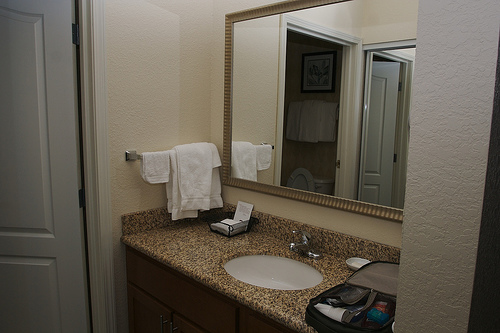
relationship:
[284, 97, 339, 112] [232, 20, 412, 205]
rack in mirror's reflection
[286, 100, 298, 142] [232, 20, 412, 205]
towels in mirror's reflection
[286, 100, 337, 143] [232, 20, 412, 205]
towels in mirror's reflection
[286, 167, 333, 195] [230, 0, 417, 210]
toilet reflected in mirror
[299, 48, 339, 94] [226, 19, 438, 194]
picture reflected in mirror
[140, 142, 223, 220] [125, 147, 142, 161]
towel on rack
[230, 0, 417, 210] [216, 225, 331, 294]
mirror above sink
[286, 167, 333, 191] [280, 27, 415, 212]
toilet reflected in mirror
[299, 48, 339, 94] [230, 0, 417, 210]
picture reflected in mirror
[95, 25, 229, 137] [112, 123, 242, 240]
wall next towels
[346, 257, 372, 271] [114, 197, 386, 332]
soap container on counter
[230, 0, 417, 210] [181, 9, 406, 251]
mirror fixed on wall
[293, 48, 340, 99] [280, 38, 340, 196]
painting hanging on wall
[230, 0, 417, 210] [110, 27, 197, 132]
mirror on wall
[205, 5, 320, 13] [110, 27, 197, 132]
frame on wall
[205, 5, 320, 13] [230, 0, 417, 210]
frame on mirror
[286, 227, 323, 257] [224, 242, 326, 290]
faucet for sink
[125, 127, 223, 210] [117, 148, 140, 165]
towel mounted rack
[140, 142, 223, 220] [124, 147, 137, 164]
towel hung on a rack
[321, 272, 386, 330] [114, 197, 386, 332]
toiletries on counter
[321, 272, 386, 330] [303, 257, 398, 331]
toiletries under bag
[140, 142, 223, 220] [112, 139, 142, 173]
towel on rack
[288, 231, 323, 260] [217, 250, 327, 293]
faucet above sink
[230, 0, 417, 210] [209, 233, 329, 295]
mirror above sink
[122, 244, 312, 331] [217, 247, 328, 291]
cabinet under sink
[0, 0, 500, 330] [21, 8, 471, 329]
bathroom in a building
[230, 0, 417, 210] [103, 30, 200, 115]
mirror on wall.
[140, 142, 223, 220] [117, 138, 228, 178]
towel hanging on rack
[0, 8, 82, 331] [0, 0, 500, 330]
door of bathroom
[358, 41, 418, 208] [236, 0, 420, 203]
door has reflection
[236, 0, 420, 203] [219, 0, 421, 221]
reflection in mirror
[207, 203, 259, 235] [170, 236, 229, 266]
basket on counter